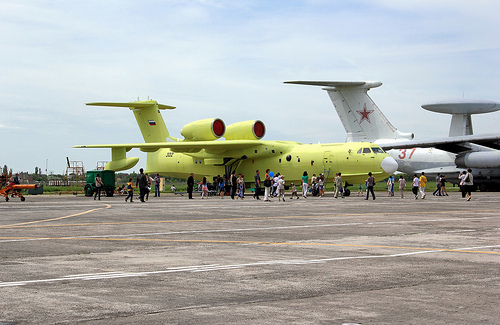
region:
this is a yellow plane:
[98, 92, 389, 204]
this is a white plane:
[308, 60, 496, 186]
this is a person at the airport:
[110, 170, 135, 206]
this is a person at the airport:
[135, 163, 150, 208]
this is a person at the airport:
[197, 175, 208, 203]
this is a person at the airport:
[235, 170, 250, 210]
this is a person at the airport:
[273, 167, 286, 198]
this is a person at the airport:
[300, 161, 313, 201]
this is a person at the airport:
[323, 160, 348, 198]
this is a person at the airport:
[360, 170, 383, 205]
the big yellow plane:
[69, 96, 399, 197]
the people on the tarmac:
[89, 165, 481, 208]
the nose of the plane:
[378, 155, 401, 177]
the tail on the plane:
[85, 100, 171, 141]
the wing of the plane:
[65, 141, 260, 173]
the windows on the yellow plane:
[355, 142, 384, 156]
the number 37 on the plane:
[395, 142, 416, 159]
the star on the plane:
[354, 100, 374, 127]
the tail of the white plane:
[275, 68, 410, 146]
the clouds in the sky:
[34, 10, 245, 85]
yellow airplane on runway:
[115, 107, 452, 202]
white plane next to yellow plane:
[301, 55, 485, 186]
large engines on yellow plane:
[188, 116, 264, 147]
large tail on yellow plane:
[110, 87, 167, 152]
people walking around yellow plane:
[172, 155, 329, 230]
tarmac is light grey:
[132, 198, 297, 323]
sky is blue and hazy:
[8, 1, 140, 111]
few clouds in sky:
[18, 17, 112, 109]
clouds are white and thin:
[25, 6, 120, 106]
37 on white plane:
[380, 146, 412, 171]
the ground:
[179, 228, 299, 313]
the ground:
[232, 186, 377, 313]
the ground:
[260, 245, 315, 317]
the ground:
[245, 199, 322, 273]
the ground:
[268, 315, 308, 321]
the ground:
[228, 217, 297, 285]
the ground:
[252, 272, 298, 323]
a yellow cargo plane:
[73, 89, 400, 202]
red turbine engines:
[175, 112, 270, 148]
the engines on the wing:
[169, 104, 275, 145]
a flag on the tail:
[147, 116, 160, 128]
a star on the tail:
[356, 100, 375, 122]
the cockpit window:
[355, 144, 386, 154]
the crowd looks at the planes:
[166, 166, 479, 211]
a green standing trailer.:
[76, 167, 123, 202]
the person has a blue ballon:
[267, 167, 274, 185]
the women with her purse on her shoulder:
[462, 165, 478, 205]